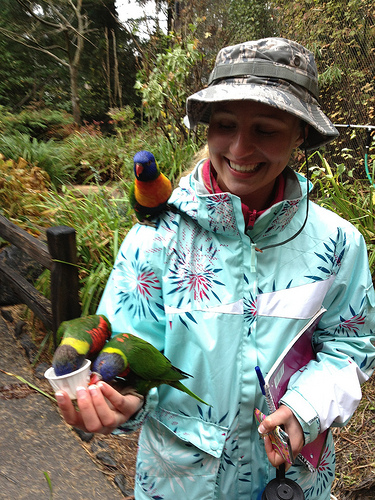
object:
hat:
[181, 37, 339, 152]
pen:
[253, 365, 278, 423]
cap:
[253, 365, 267, 394]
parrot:
[129, 150, 174, 229]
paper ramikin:
[43, 357, 92, 402]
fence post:
[45, 222, 81, 341]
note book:
[264, 307, 329, 473]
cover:
[262, 464, 307, 500]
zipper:
[246, 209, 256, 231]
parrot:
[51, 311, 112, 378]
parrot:
[89, 331, 211, 408]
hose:
[364, 155, 375, 186]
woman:
[55, 37, 375, 497]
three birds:
[52, 150, 213, 408]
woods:
[1, 4, 374, 196]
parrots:
[88, 332, 214, 409]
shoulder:
[130, 212, 191, 238]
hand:
[55, 381, 147, 436]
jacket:
[90, 157, 374, 499]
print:
[168, 242, 225, 307]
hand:
[258, 401, 304, 469]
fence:
[0, 218, 80, 349]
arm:
[89, 219, 164, 426]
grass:
[0, 128, 78, 186]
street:
[1, 312, 135, 498]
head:
[132, 150, 158, 181]